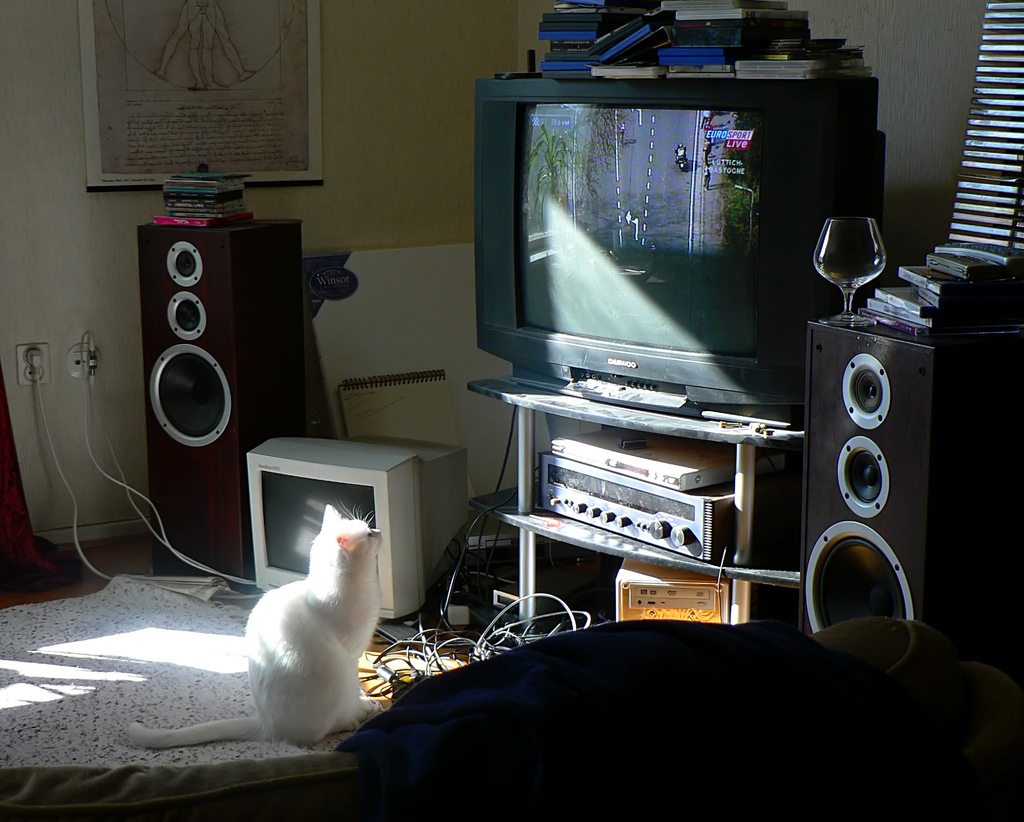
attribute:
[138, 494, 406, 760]
cat — white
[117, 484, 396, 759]
cat — white, furry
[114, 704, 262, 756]
tail — long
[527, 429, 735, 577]
stereo — old, silver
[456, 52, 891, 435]
tv — large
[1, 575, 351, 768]
rug — white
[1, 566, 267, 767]
spots — black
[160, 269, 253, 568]
speaker — large and brown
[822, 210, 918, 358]
glass — empty, wine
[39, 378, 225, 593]
cord — white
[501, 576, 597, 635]
cord — white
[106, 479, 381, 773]
cat — white, fluffy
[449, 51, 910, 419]
television — black, boxy, old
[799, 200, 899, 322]
glass — for drinking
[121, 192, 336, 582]
speaker — tall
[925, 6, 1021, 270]
cds — stacked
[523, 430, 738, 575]
dvd — black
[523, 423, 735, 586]
vhs — silver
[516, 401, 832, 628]
entertainment center — black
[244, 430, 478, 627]
monitor — short, grey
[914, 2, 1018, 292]
rack — tall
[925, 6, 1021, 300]
rack — tall